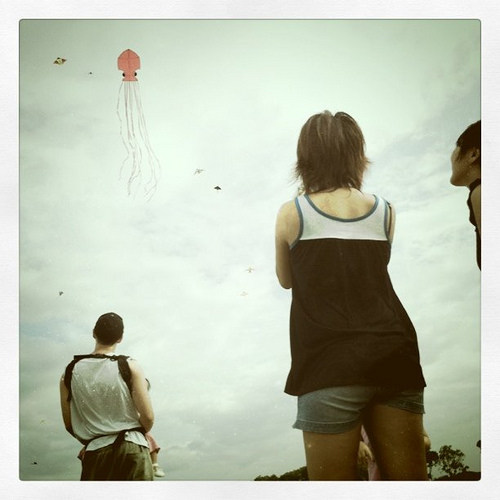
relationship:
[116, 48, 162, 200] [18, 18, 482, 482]
kite in sky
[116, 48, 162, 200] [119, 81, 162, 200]
kite has tail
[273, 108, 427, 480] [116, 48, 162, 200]
girl flying kite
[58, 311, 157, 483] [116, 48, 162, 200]
man looking at kite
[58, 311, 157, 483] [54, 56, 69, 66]
man looking at kite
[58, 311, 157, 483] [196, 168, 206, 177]
man looking at kite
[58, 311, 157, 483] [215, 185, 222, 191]
man looking at kite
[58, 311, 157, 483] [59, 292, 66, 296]
man looking at kite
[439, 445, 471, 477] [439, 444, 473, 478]
tree has leaves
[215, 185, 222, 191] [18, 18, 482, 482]
kite in sky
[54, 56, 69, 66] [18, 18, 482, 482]
kite in sky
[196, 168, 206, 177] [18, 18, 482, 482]
kite in sky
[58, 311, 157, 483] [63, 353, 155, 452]
man wearing tee shirt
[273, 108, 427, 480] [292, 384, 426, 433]
girl wearing shorts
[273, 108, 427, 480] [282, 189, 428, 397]
girl wearing tank top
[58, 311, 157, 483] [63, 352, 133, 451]
man wearing baby carrier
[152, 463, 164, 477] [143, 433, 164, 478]
shoe on leg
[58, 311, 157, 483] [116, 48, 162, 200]
man watching kite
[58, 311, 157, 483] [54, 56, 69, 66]
man watching kite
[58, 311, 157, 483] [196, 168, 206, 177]
man watching kite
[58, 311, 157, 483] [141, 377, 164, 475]
man carrying baby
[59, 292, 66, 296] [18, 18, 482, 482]
kite in sky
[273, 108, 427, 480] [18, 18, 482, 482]
girl looking at sky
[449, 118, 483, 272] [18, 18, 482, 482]
girl looking at sky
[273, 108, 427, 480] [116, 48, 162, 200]
girl looking at kite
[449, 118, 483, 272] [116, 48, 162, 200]
girl looking at kite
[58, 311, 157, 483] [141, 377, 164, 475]
man holding baby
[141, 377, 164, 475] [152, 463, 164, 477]
baby wearing shoe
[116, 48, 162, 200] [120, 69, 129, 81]
kite has eye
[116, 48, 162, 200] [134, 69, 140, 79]
kite has eye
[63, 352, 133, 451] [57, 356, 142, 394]
baby carrier on shoulders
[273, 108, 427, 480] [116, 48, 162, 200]
girl below kite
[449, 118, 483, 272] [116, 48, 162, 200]
girl below kite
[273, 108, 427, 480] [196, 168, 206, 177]
girl below kite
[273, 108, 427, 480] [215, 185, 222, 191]
girl below kite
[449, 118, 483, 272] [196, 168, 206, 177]
girl below kite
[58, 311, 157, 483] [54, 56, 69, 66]
man below kite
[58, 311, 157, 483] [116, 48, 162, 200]
man below kite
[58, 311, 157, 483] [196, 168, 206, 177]
man below kite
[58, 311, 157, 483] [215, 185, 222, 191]
man below kite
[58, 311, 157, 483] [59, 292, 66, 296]
man below kite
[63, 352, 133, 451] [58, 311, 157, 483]
baby carrier encircling man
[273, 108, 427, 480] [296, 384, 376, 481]
girl has leg